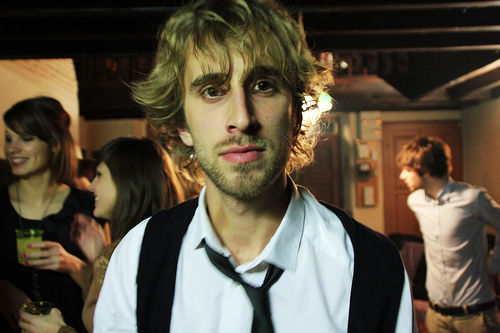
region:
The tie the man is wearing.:
[203, 246, 288, 330]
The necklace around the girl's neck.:
[12, 173, 62, 253]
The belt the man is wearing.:
[422, 299, 493, 316]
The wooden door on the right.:
[377, 118, 464, 239]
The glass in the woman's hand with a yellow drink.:
[16, 225, 40, 260]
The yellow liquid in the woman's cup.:
[16, 233, 38, 257]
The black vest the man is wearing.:
[139, 198, 403, 332]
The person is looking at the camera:
[80, 5, 405, 327]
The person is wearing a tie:
[191, 237, 297, 329]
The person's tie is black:
[196, 229, 301, 329]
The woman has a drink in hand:
[0, 84, 93, 278]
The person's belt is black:
[430, 290, 492, 323]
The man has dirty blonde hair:
[114, 5, 352, 232]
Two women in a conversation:
[5, 90, 137, 226]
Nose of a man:
[221, 95, 268, 137]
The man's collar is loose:
[186, 204, 318, 301]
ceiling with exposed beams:
[0, 1, 498, 108]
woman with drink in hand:
[3, 96, 91, 301]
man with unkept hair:
[92, 2, 412, 331]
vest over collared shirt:
[94, 187, 411, 332]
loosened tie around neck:
[191, 182, 304, 331]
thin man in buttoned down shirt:
[398, 135, 498, 331]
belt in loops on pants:
[427, 295, 499, 330]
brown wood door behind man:
[384, 117, 463, 234]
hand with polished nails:
[20, 241, 72, 271]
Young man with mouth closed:
[145, 10, 339, 206]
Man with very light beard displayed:
[204, 124, 284, 209]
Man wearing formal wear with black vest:
[115, 217, 405, 332]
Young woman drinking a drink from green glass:
[0, 95, 83, 276]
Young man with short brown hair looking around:
[393, 135, 498, 317]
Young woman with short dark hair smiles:
[85, 140, 160, 219]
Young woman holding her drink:
[16, 297, 81, 332]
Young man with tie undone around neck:
[196, 202, 330, 332]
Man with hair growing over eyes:
[157, 60, 318, 102]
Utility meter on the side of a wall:
[350, 125, 384, 214]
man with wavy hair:
[134, 1, 334, 199]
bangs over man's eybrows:
[175, 1, 295, 98]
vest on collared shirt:
[91, 181, 412, 331]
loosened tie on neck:
[196, 173, 304, 331]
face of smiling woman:
[4, 96, 73, 175]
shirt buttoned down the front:
[407, 179, 498, 304]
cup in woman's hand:
[20, 298, 65, 331]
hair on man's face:
[190, 129, 297, 198]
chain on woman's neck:
[7, 180, 66, 220]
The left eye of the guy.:
[196, 85, 222, 97]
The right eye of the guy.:
[247, 80, 274, 92]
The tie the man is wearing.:
[202, 242, 281, 331]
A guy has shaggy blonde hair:
[115, 0, 340, 206]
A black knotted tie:
[192, 230, 284, 330]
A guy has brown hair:
[391, 125, 456, 200]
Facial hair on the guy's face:
[186, 125, 297, 210]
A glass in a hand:
[6, 215, 71, 275]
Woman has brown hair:
[80, 125, 191, 240]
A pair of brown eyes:
[192, 70, 282, 102]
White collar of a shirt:
[180, 170, 312, 277]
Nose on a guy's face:
[217, 90, 267, 140]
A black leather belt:
[417, 288, 497, 320]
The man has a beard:
[130, 24, 343, 216]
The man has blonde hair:
[123, 11, 332, 206]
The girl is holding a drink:
[0, 84, 113, 280]